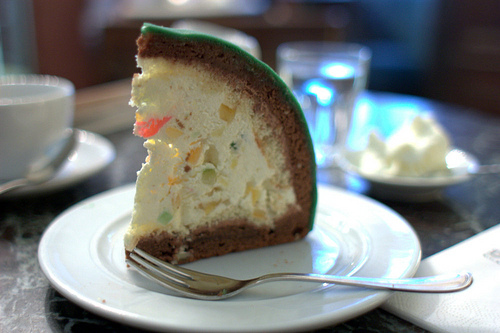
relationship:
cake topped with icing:
[123, 22, 318, 270] [140, 16, 331, 232]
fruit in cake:
[126, 114, 173, 144] [123, 18, 318, 273]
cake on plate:
[123, 22, 318, 270] [38, 177, 420, 331]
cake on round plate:
[123, 18, 318, 273] [31, 164, 421, 329]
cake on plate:
[123, 18, 318, 273] [38, 177, 420, 331]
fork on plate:
[122, 245, 473, 301] [38, 177, 420, 331]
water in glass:
[281, 65, 363, 150] [281, 41, 367, 158]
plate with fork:
[38, 177, 420, 331] [122, 245, 473, 301]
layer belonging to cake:
[123, 209, 309, 263] [108, 20, 320, 244]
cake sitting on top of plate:
[123, 22, 318, 270] [38, 177, 420, 331]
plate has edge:
[38, 177, 420, 331] [97, 188, 370, 303]